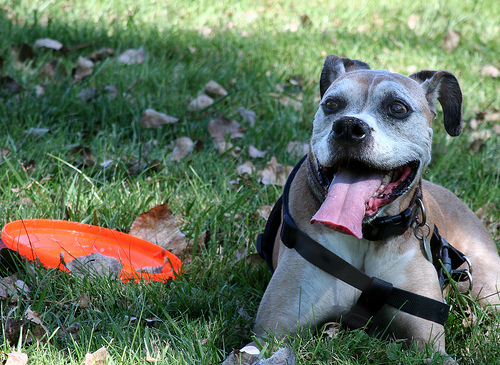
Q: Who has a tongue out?
A: Dog.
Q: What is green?
A: Grass.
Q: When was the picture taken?
A: Daytime.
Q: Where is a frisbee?
A: On the grass.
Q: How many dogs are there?
A: One.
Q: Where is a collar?
A: Around dog's neck.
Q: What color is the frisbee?
A: Orange.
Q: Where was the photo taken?
A: Outside.